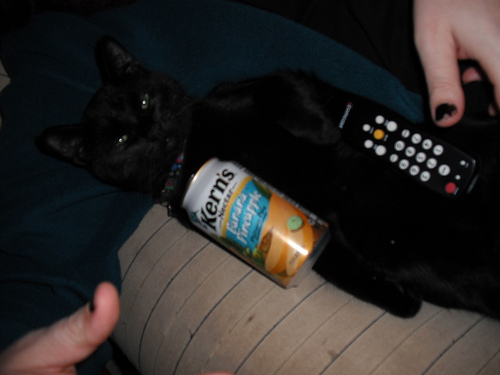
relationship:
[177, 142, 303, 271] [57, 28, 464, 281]
can laying next to cat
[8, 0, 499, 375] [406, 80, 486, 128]
person wearing nail polish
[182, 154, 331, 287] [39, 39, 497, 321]
can next to a cat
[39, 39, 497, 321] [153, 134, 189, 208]
cat with collar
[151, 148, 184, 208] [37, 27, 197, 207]
collar on cat